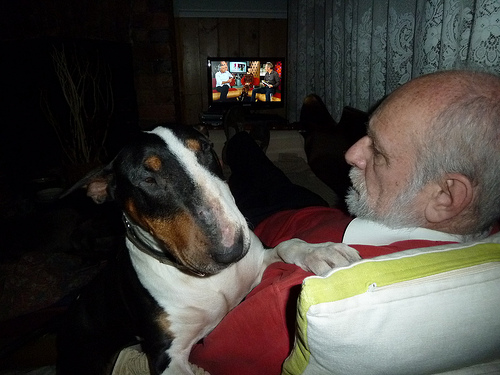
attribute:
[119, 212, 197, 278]
collar — black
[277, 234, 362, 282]
paw — white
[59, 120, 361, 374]
dog — white, black , brown 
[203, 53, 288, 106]
television — turned on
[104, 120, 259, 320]
dog — cuddling 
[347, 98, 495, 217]
hair — white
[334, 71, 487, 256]
guy — bald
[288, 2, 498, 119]
lace curtain — lace 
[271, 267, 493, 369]
pillow — white, green, striped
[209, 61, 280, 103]
tv — on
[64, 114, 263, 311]
dog — black, white, brown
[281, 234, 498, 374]
pillow — green, white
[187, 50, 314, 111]
tv — on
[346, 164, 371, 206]
moustache — white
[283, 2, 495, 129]
curtains — blue, brown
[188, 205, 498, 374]
shirt — red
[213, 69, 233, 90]
shirt — white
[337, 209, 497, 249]
collar — white 